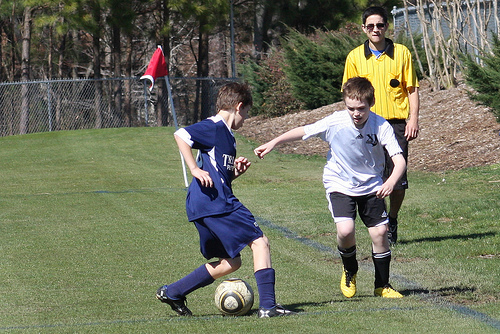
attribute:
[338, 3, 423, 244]
referee — wearing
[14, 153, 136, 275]
field — nicely trimmed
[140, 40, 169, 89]
flag — red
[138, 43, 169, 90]
flag — red, white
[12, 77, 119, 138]
fence — metal, around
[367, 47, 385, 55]
t-shirt — blue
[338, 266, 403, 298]
soccer boots — yellow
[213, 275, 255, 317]
ball — black, white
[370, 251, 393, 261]
stripes — white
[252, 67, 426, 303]
boy — brown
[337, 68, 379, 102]
hair — short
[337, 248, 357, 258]
stripe — white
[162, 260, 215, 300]
sock — tall, blue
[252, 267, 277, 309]
sock — tall, blue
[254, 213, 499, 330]
line — blue